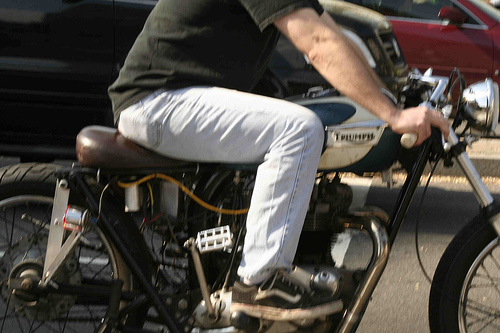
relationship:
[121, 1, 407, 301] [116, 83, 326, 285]
human wearing jeans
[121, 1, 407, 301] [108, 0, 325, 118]
human wearing shirt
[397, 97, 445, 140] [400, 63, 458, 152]
hands on handles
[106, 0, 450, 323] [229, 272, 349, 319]
human wearing shoes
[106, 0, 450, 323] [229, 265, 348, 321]
human wearing shoes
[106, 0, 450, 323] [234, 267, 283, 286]
human wearing socks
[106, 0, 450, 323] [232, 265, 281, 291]
human wearing socks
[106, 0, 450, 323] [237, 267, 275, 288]
human wearing socks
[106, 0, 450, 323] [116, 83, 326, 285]
human wearing jeans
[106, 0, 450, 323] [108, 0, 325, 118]
human in shirt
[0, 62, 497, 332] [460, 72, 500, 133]
motorcycle has light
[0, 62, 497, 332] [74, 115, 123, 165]
motorcycle has seat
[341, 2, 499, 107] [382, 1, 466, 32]
car has window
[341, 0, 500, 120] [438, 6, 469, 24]
car has mirror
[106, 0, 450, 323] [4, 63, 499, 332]
human riding motorbike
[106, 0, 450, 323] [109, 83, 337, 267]
human wearing pants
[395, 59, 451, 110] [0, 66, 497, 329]
wheel on front of bike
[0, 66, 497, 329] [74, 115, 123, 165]
bike has seat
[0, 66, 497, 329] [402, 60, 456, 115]
bike has handlebar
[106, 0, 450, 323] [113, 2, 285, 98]
human wearing shirt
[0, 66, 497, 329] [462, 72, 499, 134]
bike has headlight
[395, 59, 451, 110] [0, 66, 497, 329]
wheel on back of bike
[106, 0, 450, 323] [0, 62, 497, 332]
human riding motorcycle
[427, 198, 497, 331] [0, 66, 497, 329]
wheel on front of bike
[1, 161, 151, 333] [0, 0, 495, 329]
tire on back of bike